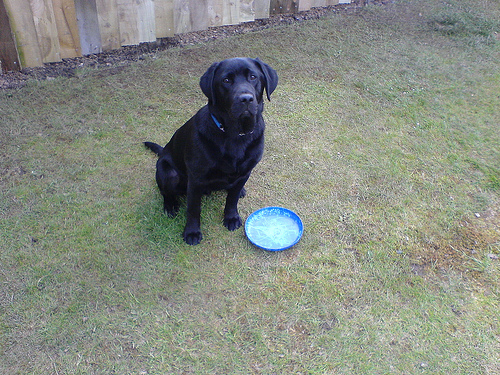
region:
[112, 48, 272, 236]
the dog on the grass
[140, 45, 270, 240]
the dog is black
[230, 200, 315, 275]
the frisbee on the grass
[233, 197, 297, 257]
the frisbee is blue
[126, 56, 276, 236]
the dog is sitting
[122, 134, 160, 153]
tail of the dog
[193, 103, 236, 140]
the collar on the dog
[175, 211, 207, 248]
paw of the dog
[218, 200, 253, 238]
the paw of the dog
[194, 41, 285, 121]
the head of the dog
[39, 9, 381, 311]
black dog with frisbee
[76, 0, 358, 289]
the dog wants to play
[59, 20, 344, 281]
there is one dog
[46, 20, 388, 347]
the dog is in a yard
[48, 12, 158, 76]
the fence is wood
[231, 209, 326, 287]
the frisbee is blue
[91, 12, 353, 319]
the dog collar is blue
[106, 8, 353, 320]
this is a black dog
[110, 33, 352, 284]
dog playing with frisbee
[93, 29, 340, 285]
the dog breed is lab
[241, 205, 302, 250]
A blue bowl on the ground.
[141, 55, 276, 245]
A black dog sitting in the grass.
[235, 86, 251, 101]
A nose on a dog.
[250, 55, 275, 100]
A ear on a dog.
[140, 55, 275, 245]
A dog wearing a blue collar.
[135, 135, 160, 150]
The tail on a dog.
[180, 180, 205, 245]
A paw on a dog.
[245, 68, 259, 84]
The eye on a dog.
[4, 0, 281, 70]
A brown wooden fence.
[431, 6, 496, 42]
A patch of grass.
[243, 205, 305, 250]
Blue bowl filled with water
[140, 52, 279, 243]
Large black Labrador type dog with blue collar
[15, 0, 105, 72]
Aged planks of wooden yard fencing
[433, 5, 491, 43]
Patch of fluffy green grass near fence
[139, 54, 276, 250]
Large black dog sitting in the grass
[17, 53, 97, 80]
Brown rock at the base of wooden fence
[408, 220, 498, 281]
Brown patch of grass in sparse lawn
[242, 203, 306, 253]
Overturned blue frisbee filled with water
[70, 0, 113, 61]
Unmatching, oddly colored wooden fence plank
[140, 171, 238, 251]
Patch of fluffy grass being sat on by black dog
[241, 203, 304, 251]
A blue dog's bowl.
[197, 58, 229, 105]
A black dog ear.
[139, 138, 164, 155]
A black dog tail.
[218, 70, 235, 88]
The eye on a dog.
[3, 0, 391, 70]
A wood fence by the grass.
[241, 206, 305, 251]
A bowl of water.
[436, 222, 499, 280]
Brown patch of grass.